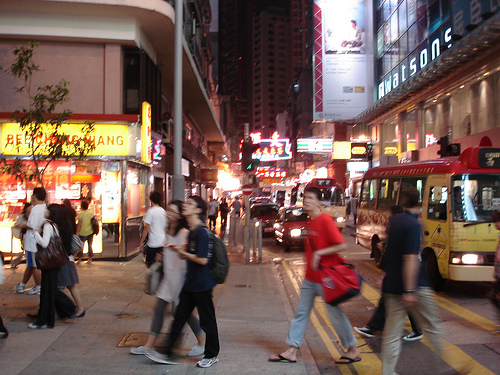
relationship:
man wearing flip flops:
[264, 181, 362, 367] [348, 187, 434, 335]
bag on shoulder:
[34, 222, 70, 270] [42, 220, 53, 230]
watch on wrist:
[402, 289, 416, 295] [404, 285, 416, 299]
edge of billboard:
[311, 100, 326, 123] [310, 0, 379, 127]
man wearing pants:
[264, 181, 362, 367] [285, 279, 360, 350]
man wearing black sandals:
[248, 170, 355, 360] [264, 349, 366, 365]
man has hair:
[135, 192, 225, 372] [184, 190, 211, 220]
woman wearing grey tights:
[127, 200, 194, 374] [154, 228, 191, 305]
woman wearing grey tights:
[129, 198, 206, 356] [151, 295, 210, 345]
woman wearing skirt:
[49, 204, 86, 316] [67, 265, 74, 283]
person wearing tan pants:
[375, 192, 453, 368] [371, 277, 475, 373]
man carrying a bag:
[264, 181, 362, 367] [312, 250, 367, 311]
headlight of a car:
[282, 227, 306, 237] [276, 199, 334, 244]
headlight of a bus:
[445, 245, 492, 275] [345, 130, 494, 300]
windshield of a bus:
[452, 171, 499, 223] [345, 130, 494, 300]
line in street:
[437, 289, 498, 341] [281, 242, 433, 372]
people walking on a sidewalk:
[206, 194, 240, 226] [0, 214, 315, 374]